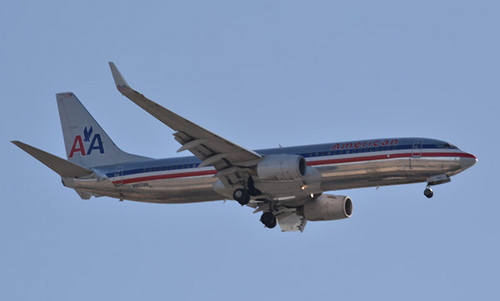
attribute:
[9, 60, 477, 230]
plane — flying, silver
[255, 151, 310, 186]
engine — white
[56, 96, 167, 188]
tail — white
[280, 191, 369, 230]
engine —  the right, White 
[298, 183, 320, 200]
lights — white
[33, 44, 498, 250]
plane — large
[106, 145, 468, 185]
stripes — blue, white, red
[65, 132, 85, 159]
letter a — red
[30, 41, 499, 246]
jets — silver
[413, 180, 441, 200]
wheel — black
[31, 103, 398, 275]
plane — red, white, blue, silver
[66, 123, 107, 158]
lettering — red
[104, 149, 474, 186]
stripes — red, white